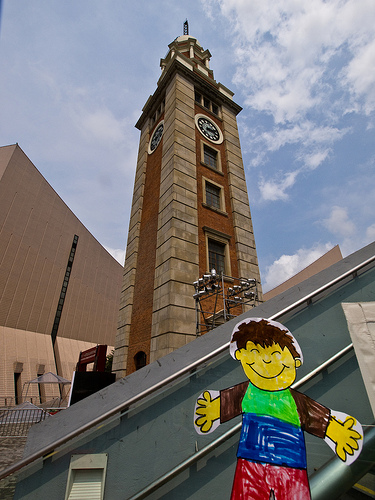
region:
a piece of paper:
[182, 313, 360, 495]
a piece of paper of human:
[185, 300, 365, 497]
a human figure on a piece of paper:
[174, 306, 365, 498]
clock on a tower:
[187, 105, 230, 144]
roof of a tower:
[165, 13, 218, 66]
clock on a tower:
[144, 114, 172, 152]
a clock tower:
[103, 6, 276, 354]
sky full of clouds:
[256, 33, 371, 100]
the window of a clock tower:
[195, 134, 231, 172]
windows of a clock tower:
[195, 173, 235, 212]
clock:
[197, 104, 241, 156]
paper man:
[204, 315, 363, 491]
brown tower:
[124, 17, 266, 308]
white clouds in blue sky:
[11, 20, 30, 36]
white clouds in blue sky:
[263, 145, 310, 189]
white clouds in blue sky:
[278, 178, 308, 200]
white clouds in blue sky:
[296, 158, 340, 190]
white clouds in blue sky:
[301, 47, 353, 100]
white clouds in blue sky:
[71, 135, 103, 161]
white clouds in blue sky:
[62, 72, 106, 98]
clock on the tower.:
[191, 111, 225, 144]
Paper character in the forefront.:
[189, 312, 364, 498]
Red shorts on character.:
[225, 455, 313, 498]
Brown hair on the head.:
[230, 318, 299, 391]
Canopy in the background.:
[21, 367, 70, 408]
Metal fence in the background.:
[0, 403, 65, 438]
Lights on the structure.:
[188, 265, 258, 326]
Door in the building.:
[197, 171, 229, 216]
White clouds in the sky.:
[193, 0, 373, 285]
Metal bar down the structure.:
[0, 251, 372, 483]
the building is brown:
[97, 11, 283, 380]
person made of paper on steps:
[188, 301, 364, 498]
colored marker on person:
[172, 311, 364, 498]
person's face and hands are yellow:
[163, 304, 366, 494]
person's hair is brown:
[215, 307, 319, 360]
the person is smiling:
[222, 312, 313, 390]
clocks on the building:
[138, 111, 241, 155]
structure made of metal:
[188, 250, 259, 332]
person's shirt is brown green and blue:
[209, 373, 325, 478]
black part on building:
[39, 226, 89, 349]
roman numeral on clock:
[204, 118, 209, 123]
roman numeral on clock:
[208, 119, 213, 127]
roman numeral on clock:
[212, 125, 217, 130]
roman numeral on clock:
[212, 135, 218, 141]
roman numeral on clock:
[203, 130, 208, 139]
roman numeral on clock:
[200, 126, 205, 133]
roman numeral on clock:
[197, 124, 202, 129]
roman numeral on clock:
[197, 119, 202, 125]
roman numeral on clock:
[199, 117, 204, 123]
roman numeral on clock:
[156, 125, 162, 134]